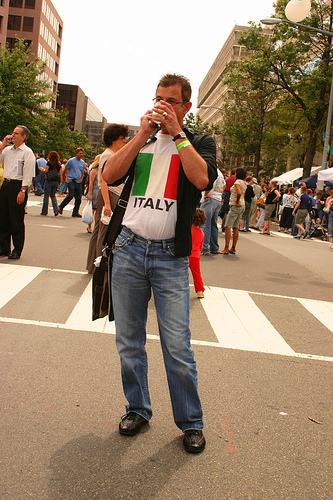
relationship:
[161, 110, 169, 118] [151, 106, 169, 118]
ring on finger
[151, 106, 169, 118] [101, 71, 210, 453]
finger on man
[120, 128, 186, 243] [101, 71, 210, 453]
shirt on man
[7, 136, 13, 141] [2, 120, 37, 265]
cell phone on man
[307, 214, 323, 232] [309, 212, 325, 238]
baby in stroller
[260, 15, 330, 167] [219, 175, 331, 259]
street light above chair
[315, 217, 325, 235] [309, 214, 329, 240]
baby in stroller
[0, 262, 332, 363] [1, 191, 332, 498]
white lines on street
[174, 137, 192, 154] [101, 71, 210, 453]
armband on man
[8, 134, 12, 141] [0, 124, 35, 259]
cell phone on man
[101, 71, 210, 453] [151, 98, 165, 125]
man has cup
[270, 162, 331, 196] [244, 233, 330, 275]
tents on street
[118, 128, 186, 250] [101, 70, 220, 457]
shirt on man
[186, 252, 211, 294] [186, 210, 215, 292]
pants on child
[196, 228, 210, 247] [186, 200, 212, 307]
shirt on child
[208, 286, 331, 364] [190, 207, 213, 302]
crosswalk under child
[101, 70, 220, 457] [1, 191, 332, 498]
man standing on street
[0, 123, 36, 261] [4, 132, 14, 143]
man talking on cellphone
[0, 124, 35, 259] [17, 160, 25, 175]
man carrying newspaper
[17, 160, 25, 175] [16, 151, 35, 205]
newspaper under arm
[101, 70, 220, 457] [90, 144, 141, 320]
man carrying bag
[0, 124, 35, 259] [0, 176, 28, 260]
man wearing pants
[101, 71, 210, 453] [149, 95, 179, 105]
man wearing glasses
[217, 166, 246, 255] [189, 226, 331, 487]
woman standing on street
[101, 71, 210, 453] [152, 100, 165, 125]
man holds cup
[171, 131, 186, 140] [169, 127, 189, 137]
wrist watch on wrist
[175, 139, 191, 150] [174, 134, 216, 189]
bracelet on arm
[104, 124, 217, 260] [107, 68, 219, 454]
toddler behind man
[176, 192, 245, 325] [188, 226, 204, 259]
toddler wears shirt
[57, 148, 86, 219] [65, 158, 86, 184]
man with shirt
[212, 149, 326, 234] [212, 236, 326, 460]
people gared in street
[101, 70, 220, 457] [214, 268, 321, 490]
man in center of a street